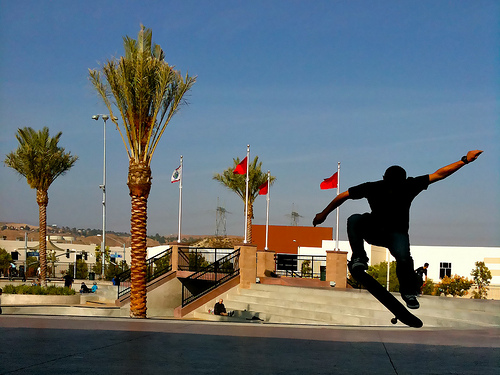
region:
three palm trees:
[34, 43, 306, 373]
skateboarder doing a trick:
[332, 130, 462, 357]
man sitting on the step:
[183, 297, 227, 334]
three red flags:
[224, 153, 359, 269]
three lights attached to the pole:
[74, 104, 142, 138]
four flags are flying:
[162, 140, 358, 275]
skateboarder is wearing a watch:
[428, 119, 498, 169]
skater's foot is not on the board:
[370, 295, 431, 353]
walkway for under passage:
[143, 251, 237, 329]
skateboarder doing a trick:
[408, 248, 451, 299]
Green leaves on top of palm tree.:
[106, 51, 180, 133]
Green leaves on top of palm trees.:
[20, 139, 79, 192]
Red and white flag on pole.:
[162, 162, 200, 184]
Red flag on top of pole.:
[221, 148, 262, 185]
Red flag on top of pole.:
[305, 167, 351, 192]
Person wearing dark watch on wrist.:
[457, 145, 467, 166]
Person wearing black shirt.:
[350, 187, 432, 255]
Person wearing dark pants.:
[346, 223, 425, 270]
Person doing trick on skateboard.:
[328, 225, 433, 344]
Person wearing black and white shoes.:
[325, 287, 440, 331]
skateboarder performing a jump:
[295, 36, 482, 354]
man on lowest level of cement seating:
[187, 261, 490, 327]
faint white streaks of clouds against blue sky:
[135, 50, 475, 160]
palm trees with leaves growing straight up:
[80, 26, 192, 311]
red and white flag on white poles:
[150, 146, 350, 216]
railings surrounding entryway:
[111, 235, 246, 307]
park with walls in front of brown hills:
[1, 216, 168, 298]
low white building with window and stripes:
[295, 230, 495, 290]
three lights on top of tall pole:
[80, 90, 120, 275]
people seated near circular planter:
[25, 252, 115, 312]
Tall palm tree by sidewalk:
[87, 32, 196, 316]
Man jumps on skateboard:
[292, 145, 495, 332]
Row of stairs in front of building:
[255, 276, 361, 341]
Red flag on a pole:
[230, 137, 261, 247]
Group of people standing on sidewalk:
[3, 244, 140, 276]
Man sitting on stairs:
[194, 294, 274, 339]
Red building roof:
[237, 215, 359, 276]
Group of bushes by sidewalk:
[435, 257, 498, 300]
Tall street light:
[89, 112, 127, 269]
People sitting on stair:
[65, 273, 106, 305]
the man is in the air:
[345, 170, 435, 308]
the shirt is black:
[355, 175, 422, 226]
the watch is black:
[457, 150, 470, 175]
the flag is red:
[310, 171, 341, 191]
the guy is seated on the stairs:
[205, 290, 258, 336]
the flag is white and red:
[167, 163, 188, 185]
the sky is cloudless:
[246, 88, 442, 171]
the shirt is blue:
[87, 270, 115, 286]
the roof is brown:
[275, 221, 330, 251]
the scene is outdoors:
[7, 9, 493, 355]